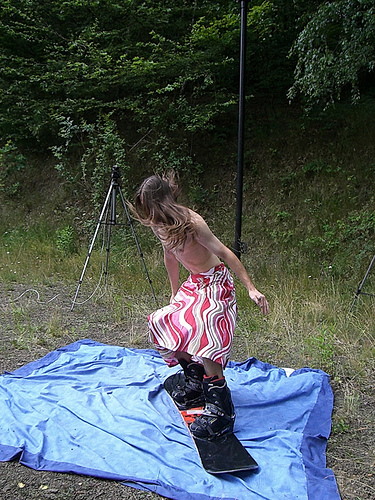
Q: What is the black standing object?
A: Tripod.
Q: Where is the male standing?
A: Snowboard.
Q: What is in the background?
A: Green bushes and trees.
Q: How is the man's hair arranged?
A: Blowing in the breeze.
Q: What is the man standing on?
A: A snowboard.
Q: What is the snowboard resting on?
A: A blue blanket.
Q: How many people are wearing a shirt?
A: None.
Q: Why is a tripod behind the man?
A: To take a picture.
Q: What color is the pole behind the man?
A: Black.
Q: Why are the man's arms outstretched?
A: He is balancing.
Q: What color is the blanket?
A: Blue.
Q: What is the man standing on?
A: Snowboard.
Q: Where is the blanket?
A: On ground.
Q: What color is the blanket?
A: Blue.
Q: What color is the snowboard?
A: Black.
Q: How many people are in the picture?
A: 1.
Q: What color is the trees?
A: Green.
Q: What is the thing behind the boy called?
A: A tri~stand.